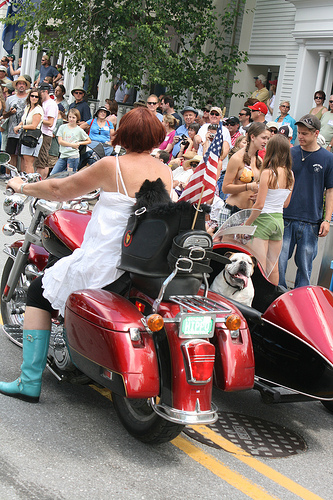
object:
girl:
[210, 122, 273, 220]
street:
[4, 333, 332, 497]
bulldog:
[202, 234, 269, 323]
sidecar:
[208, 243, 330, 415]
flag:
[171, 121, 224, 204]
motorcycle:
[1, 173, 255, 445]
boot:
[1, 328, 54, 404]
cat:
[129, 177, 176, 218]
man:
[280, 113, 332, 289]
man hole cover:
[180, 410, 311, 459]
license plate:
[180, 313, 218, 340]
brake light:
[145, 314, 166, 332]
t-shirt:
[285, 147, 332, 226]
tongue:
[234, 271, 251, 287]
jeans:
[279, 216, 319, 290]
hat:
[295, 114, 326, 131]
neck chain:
[298, 146, 321, 164]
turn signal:
[128, 325, 146, 346]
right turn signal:
[228, 328, 243, 341]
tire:
[113, 298, 185, 445]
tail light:
[223, 313, 246, 337]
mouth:
[228, 266, 250, 289]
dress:
[42, 154, 181, 319]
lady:
[1, 104, 180, 403]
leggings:
[24, 273, 56, 313]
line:
[187, 420, 331, 499]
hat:
[247, 101, 269, 116]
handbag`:
[16, 125, 43, 150]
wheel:
[3, 244, 54, 329]